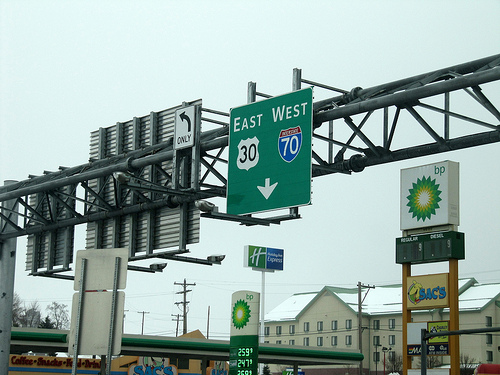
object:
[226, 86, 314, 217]
sign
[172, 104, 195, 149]
sign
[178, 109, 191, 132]
left arrow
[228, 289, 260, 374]
bp sign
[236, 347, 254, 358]
price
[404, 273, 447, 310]
sac's sign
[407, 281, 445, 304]
logo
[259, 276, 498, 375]
hotel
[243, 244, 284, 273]
sign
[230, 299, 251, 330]
logo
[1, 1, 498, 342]
sky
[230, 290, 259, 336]
background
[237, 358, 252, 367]
price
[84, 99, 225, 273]
highway sign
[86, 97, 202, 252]
back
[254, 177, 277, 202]
down arrow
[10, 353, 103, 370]
letters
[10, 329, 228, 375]
building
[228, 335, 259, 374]
background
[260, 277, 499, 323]
roof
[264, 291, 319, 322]
snow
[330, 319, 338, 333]
window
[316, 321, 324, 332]
window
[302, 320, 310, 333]
window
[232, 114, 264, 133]
word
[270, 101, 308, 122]
word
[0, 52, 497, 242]
beam